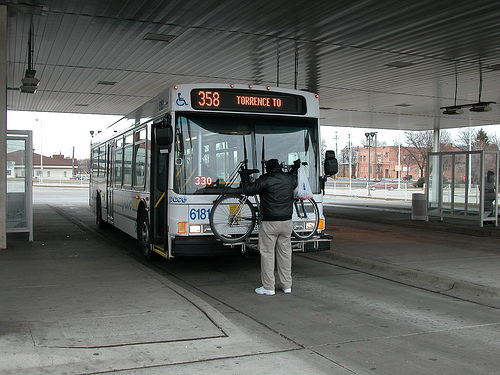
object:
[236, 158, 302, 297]
person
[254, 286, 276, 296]
shoe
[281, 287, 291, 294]
shoe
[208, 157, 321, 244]
bike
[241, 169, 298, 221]
coat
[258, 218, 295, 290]
pants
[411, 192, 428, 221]
trash can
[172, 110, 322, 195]
windshield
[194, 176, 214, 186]
330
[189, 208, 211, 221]
6181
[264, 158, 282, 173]
hat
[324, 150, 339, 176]
mirror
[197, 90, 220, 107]
358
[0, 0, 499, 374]
bus stop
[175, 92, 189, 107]
handicap symbol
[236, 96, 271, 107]
torrence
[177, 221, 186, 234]
lights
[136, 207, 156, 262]
tire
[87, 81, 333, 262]
bus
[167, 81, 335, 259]
front